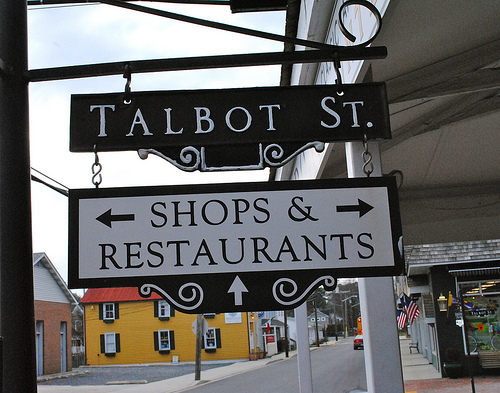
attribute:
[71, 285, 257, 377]
building — yellow, orange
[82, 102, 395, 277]
signs — black, white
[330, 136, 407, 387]
sign holder — iron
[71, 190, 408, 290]
sign — black, white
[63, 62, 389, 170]
sign — black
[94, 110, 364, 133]
writing — white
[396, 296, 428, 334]
flags — american, hanging, small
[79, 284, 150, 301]
roof — red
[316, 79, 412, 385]
pole — white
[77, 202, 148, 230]
arrow — black, upwards, white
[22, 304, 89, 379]
building — red, brick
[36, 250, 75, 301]
roof — white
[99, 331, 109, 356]
shutters — black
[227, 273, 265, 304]
arrow — white, up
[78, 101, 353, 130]
signage — black, white